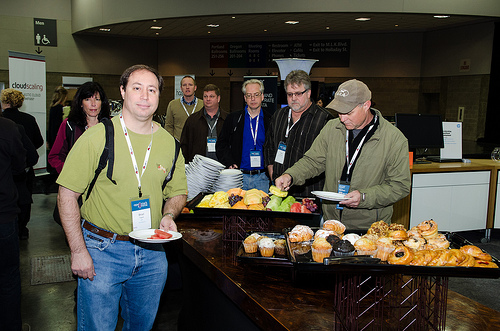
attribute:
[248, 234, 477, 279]
plate — large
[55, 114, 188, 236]
shirt — green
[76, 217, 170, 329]
jeans — blue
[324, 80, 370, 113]
cap — khaki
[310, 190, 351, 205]
plate — white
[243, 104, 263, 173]
shirt — blue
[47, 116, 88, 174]
shirt — pink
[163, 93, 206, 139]
sweater — green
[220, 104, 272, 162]
jacket — black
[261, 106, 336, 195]
shirt — striped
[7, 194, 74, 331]
ground — concrete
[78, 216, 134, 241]
belt — brown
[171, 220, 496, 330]
table — wood, brown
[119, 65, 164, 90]
hair — short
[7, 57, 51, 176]
banner — white